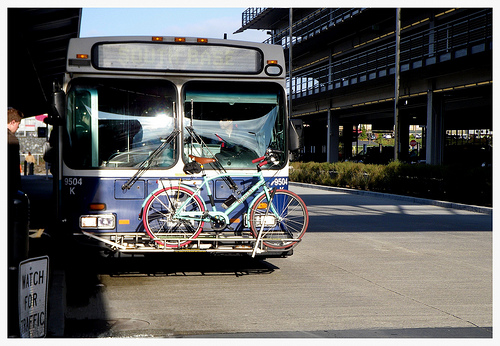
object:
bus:
[52, 35, 296, 262]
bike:
[139, 154, 311, 250]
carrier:
[79, 230, 301, 257]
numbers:
[64, 178, 68, 185]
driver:
[212, 114, 243, 152]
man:
[7, 109, 23, 209]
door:
[51, 82, 62, 236]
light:
[81, 215, 99, 229]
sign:
[15, 255, 50, 338]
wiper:
[121, 128, 180, 192]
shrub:
[290, 161, 444, 197]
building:
[236, 0, 490, 180]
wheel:
[142, 186, 205, 247]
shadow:
[70, 251, 278, 277]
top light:
[151, 36, 163, 41]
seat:
[188, 154, 215, 163]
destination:
[97, 41, 261, 73]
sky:
[78, 7, 269, 42]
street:
[68, 192, 492, 337]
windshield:
[65, 79, 174, 170]